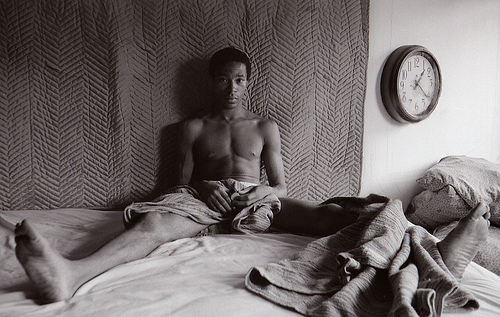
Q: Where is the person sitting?
A: On a bed.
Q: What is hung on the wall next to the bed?
A: Clock.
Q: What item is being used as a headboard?
A: A blanket.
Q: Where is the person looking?
A: Directly at camera.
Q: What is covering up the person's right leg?
A: Blanket.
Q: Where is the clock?
A: Hung on wall.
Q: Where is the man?
A: On his bed.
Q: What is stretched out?
A: A leg.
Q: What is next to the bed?
A: Pillows.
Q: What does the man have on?
A: A blanket.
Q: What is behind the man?
A: A blanket on the wall.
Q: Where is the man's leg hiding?
A: Under the blanket.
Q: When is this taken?
A: 1:21.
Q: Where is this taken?
A: In a bedroom.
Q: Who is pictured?
A: A man.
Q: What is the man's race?
A: Black.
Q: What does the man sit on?
A: A bed.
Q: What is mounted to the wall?
A: A clock.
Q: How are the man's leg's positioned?
A: Extended to either side.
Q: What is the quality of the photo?
A: Black and white.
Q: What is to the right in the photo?
A: Pillows.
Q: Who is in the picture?
A: A man.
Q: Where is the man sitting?
A: The bed.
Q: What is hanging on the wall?
A: A clock.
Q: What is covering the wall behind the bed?
A: A quilt.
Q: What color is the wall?
A: White.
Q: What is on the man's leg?
A: Blanket.